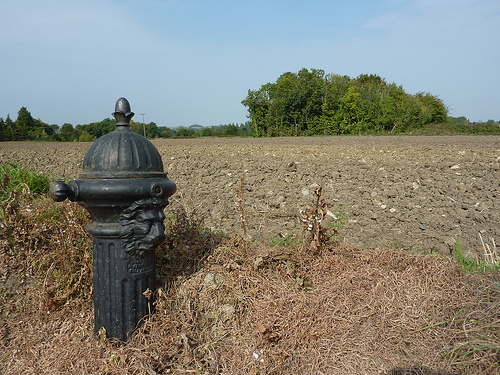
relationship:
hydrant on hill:
[46, 98, 175, 344] [0, 135, 498, 373]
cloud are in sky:
[7, 0, 495, 129] [3, 1, 491, 118]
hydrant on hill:
[46, 98, 175, 344] [94, 47, 464, 130]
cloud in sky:
[7, 0, 495, 129] [3, 1, 491, 118]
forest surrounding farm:
[2, 62, 499, 142] [1, 128, 498, 274]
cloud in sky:
[7, 12, 197, 72] [3, 1, 491, 118]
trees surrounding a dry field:
[245, 66, 457, 134] [2, 135, 498, 374]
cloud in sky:
[7, 0, 495, 129] [0, 0, 490, 65]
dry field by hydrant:
[2, 135, 498, 374] [53, 94, 179, 346]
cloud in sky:
[7, 0, 495, 129] [191, 31, 256, 74]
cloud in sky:
[7, 0, 495, 129] [434, 12, 494, 96]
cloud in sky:
[7, 0, 495, 129] [205, 7, 402, 61]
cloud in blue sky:
[7, 0, 495, 129] [106, 13, 230, 98]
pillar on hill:
[51, 97, 178, 340] [10, 165, 495, 373]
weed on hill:
[299, 185, 338, 248] [0, 135, 498, 373]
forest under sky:
[2, 62, 499, 142] [1, 2, 497, 141]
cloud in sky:
[7, 0, 495, 129] [0, 0, 499, 128]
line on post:
[110, 131, 124, 173] [48, 97, 185, 351]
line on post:
[121, 132, 138, 171] [48, 97, 185, 351]